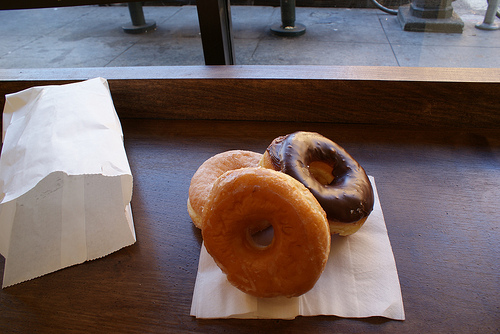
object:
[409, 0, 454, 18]
piller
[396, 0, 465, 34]
base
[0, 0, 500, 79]
window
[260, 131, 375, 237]
donut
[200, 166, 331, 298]
donut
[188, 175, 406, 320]
napkin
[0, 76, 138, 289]
bag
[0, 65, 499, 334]
counter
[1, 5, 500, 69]
sidewalk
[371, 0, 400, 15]
bicycle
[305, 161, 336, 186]
whole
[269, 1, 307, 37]
post